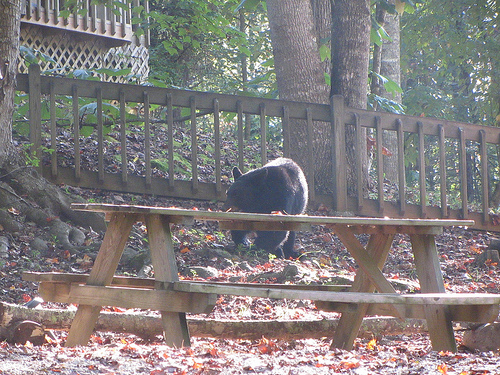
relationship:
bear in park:
[226, 156, 312, 263] [0, 146, 500, 374]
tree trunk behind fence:
[264, 1, 403, 193] [0, 72, 500, 234]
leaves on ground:
[4, 191, 498, 375] [0, 265, 495, 373]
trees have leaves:
[5, 4, 498, 205] [4, 191, 498, 375]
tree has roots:
[2, 2, 21, 233] [0, 164, 105, 235]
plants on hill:
[5, 89, 276, 186] [7, 91, 274, 197]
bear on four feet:
[226, 156, 312, 263] [225, 234, 310, 260]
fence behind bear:
[0, 72, 500, 234] [226, 156, 312, 263]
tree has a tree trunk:
[269, 2, 373, 195] [264, 1, 403, 193]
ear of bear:
[229, 166, 245, 182] [226, 156, 312, 263]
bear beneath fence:
[226, 156, 312, 263] [0, 72, 500, 234]